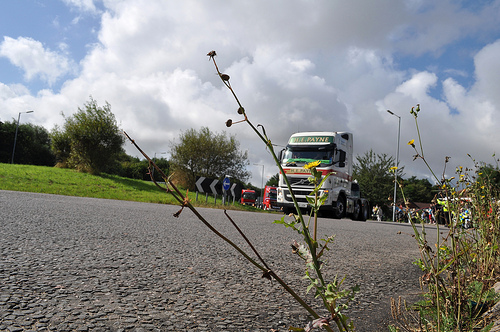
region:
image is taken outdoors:
[41, 140, 496, 306]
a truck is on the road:
[275, 126, 370, 226]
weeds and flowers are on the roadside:
[128, 50, 498, 328]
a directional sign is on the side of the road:
[181, 168, 239, 213]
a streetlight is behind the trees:
[10, 103, 45, 159]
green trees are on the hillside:
[1, 98, 472, 228]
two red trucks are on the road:
[237, 180, 287, 216]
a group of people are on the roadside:
[370, 195, 440, 226]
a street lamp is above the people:
[365, 100, 421, 230]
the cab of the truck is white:
[275, 126, 363, 216]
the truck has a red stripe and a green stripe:
[275, 126, 355, 219]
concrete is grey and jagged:
[38, 183, 291, 314]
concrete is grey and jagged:
[118, 214, 255, 329]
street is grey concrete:
[30, 188, 451, 329]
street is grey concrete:
[85, 231, 250, 289]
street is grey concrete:
[88, 257, 391, 329]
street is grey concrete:
[111, 215, 353, 322]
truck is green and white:
[265, 112, 353, 215]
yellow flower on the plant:
[406, 138, 416, 148]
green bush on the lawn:
[40, 95, 131, 182]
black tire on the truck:
[331, 190, 346, 215]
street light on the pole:
[384, 107, 394, 116]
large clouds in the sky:
[53, 13, 497, 147]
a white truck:
[284, 132, 365, 205]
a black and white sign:
[194, 172, 221, 192]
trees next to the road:
[58, 113, 242, 178]